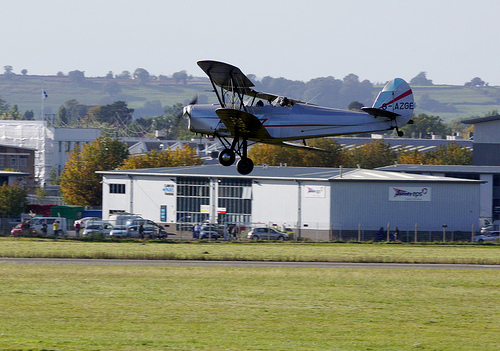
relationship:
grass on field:
[31, 276, 218, 346] [7, 250, 488, 348]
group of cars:
[0, 212, 289, 240] [10, 209, 300, 247]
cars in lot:
[10, 209, 300, 247] [2, 210, 324, 250]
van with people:
[11, 213, 63, 239] [38, 222, 59, 237]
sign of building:
[374, 180, 444, 212] [97, 155, 481, 246]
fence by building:
[339, 218, 488, 245] [97, 155, 481, 246]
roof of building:
[100, 159, 483, 192] [97, 155, 481, 246]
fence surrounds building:
[6, 219, 492, 254] [97, 155, 481, 246]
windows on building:
[183, 163, 263, 217] [124, 150, 395, 240]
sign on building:
[374, 180, 444, 212] [275, 155, 476, 250]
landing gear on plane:
[185, 137, 262, 186] [166, 62, 453, 187]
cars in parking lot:
[10, 209, 300, 247] [15, 221, 235, 253]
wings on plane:
[195, 52, 257, 127] [156, 49, 466, 218]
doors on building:
[169, 172, 257, 228] [94, 153, 499, 280]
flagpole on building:
[32, 92, 61, 117] [2, 107, 180, 209]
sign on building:
[374, 180, 444, 212] [235, 153, 461, 255]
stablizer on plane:
[366, 73, 436, 130] [166, 52, 395, 176]